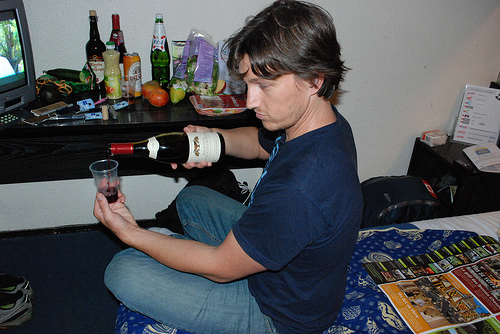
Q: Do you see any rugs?
A: No, there are no rugs.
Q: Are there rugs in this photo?
A: No, there are no rugs.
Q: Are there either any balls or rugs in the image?
A: No, there are no rugs or balls.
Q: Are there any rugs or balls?
A: No, there are no rugs or balls.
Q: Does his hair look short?
A: Yes, the hair is short.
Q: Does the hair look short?
A: Yes, the hair is short.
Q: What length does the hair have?
A: The hair has short length.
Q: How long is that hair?
A: The hair is short.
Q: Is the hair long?
A: No, the hair is short.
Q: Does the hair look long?
A: No, the hair is short.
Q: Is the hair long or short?
A: The hair is short.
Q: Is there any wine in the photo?
A: Yes, there is wine.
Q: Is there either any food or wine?
A: Yes, there is wine.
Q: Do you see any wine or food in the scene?
A: Yes, there is wine.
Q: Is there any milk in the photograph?
A: No, there is no milk.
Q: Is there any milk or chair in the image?
A: No, there are no milk or chairs.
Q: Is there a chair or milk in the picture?
A: No, there are no milk or chairs.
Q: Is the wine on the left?
A: Yes, the wine is on the left of the image.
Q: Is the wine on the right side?
A: No, the wine is on the left of the image.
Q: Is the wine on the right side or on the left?
A: The wine is on the left of the image.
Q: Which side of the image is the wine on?
A: The wine is on the left of the image.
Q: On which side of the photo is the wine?
A: The wine is on the left of the image.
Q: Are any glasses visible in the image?
A: No, there are no glasses.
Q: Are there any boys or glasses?
A: No, there are no glasses or boys.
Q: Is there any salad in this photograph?
A: Yes, there is salad.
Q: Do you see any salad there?
A: Yes, there is salad.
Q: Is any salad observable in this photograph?
A: Yes, there is salad.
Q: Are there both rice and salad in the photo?
A: No, there is salad but no rice.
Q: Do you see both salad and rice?
A: No, there is salad but no rice.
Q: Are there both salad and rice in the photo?
A: No, there is salad but no rice.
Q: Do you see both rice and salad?
A: No, there is salad but no rice.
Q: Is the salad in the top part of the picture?
A: Yes, the salad is in the top of the image.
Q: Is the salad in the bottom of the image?
A: No, the salad is in the top of the image.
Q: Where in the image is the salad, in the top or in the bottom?
A: The salad is in the top of the image.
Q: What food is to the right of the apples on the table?
A: The food is salad.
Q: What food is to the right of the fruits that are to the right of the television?
A: The food is salad.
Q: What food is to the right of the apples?
A: The food is salad.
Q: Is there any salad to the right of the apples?
A: Yes, there is salad to the right of the apples.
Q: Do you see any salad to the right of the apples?
A: Yes, there is salad to the right of the apples.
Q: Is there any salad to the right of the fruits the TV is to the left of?
A: Yes, there is salad to the right of the apples.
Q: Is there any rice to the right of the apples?
A: No, there is salad to the right of the apples.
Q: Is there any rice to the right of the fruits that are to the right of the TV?
A: No, there is salad to the right of the apples.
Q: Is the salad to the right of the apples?
A: Yes, the salad is to the right of the apples.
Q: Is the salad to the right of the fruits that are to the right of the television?
A: Yes, the salad is to the right of the apples.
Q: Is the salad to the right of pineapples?
A: No, the salad is to the right of the apples.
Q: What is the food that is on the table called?
A: The food is salad.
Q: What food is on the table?
A: The food is salad.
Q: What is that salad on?
A: The salad is on the table.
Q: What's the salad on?
A: The salad is on the table.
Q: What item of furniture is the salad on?
A: The salad is on the table.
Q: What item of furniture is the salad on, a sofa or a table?
A: The salad is on a table.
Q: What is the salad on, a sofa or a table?
A: The salad is on a table.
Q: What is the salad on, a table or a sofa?
A: The salad is on a table.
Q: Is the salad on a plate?
A: No, the salad is on the table.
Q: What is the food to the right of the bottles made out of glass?
A: The food is salad.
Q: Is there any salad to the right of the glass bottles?
A: Yes, there is salad to the right of the bottles.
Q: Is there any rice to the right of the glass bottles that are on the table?
A: No, there is salad to the right of the bottles.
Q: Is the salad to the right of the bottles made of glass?
A: Yes, the salad is to the right of the bottles.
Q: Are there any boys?
A: No, there are no boys.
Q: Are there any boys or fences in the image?
A: No, there are no boys or fences.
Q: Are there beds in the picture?
A: Yes, there is a bed.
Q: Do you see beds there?
A: Yes, there is a bed.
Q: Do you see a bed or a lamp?
A: Yes, there is a bed.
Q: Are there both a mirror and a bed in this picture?
A: No, there is a bed but no mirrors.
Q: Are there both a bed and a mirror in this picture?
A: No, there is a bed but no mirrors.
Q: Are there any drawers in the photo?
A: No, there are no drawers.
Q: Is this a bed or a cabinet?
A: This is a bed.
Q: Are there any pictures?
A: No, there are no pictures.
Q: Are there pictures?
A: No, there are no pictures.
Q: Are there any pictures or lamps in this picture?
A: No, there are no pictures or lamps.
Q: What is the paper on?
A: The paper is on the bed.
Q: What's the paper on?
A: The paper is on the bed.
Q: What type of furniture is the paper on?
A: The paper is on the bed.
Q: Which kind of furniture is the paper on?
A: The paper is on the bed.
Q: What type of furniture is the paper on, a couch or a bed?
A: The paper is on a bed.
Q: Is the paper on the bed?
A: Yes, the paper is on the bed.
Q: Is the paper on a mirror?
A: No, the paper is on the bed.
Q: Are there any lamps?
A: No, there are no lamps.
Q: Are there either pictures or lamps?
A: No, there are no lamps or pictures.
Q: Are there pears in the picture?
A: Yes, there is a pear.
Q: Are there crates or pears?
A: Yes, there is a pear.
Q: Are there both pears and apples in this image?
A: Yes, there are both a pear and apples.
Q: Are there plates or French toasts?
A: No, there are no plates or French toasts.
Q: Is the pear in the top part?
A: Yes, the pear is in the top of the image.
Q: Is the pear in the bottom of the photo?
A: No, the pear is in the top of the image.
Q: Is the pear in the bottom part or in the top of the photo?
A: The pear is in the top of the image.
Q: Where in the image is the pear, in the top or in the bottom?
A: The pear is in the top of the image.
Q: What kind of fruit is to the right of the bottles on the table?
A: The fruit is a pear.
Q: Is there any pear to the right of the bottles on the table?
A: Yes, there is a pear to the right of the bottles.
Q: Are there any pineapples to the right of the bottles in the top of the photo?
A: No, there is a pear to the right of the bottles.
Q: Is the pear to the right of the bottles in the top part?
A: Yes, the pear is to the right of the bottles.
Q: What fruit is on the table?
A: The fruit is a pear.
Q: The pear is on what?
A: The pear is on the table.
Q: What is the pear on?
A: The pear is on the table.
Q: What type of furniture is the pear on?
A: The pear is on the table.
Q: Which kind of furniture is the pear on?
A: The pear is on the table.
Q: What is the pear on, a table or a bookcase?
A: The pear is on a table.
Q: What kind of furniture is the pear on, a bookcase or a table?
A: The pear is on a table.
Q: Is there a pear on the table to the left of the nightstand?
A: Yes, there is a pear on the table.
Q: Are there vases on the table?
A: No, there is a pear on the table.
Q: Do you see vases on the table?
A: No, there is a pear on the table.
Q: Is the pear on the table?
A: Yes, the pear is on the table.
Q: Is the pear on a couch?
A: No, the pear is on the table.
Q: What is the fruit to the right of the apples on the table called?
A: The fruit is a pear.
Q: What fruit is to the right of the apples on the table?
A: The fruit is a pear.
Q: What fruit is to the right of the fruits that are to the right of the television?
A: The fruit is a pear.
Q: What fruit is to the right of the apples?
A: The fruit is a pear.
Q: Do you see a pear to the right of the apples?
A: Yes, there is a pear to the right of the apples.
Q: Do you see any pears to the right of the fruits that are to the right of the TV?
A: Yes, there is a pear to the right of the apples.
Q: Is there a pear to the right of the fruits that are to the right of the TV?
A: Yes, there is a pear to the right of the apples.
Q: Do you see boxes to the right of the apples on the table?
A: No, there is a pear to the right of the apples.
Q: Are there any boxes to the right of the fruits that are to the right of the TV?
A: No, there is a pear to the right of the apples.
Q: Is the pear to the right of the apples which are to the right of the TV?
A: Yes, the pear is to the right of the apples.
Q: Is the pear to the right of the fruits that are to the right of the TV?
A: Yes, the pear is to the right of the apples.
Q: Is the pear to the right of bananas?
A: No, the pear is to the right of the apples.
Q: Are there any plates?
A: No, there are no plates.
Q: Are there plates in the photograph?
A: No, there are no plates.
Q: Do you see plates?
A: No, there are no plates.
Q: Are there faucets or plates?
A: No, there are no plates or faucets.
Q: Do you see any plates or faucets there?
A: No, there are no plates or faucets.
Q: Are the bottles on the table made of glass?
A: Yes, the bottles are made of glass.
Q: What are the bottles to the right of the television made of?
A: The bottles are made of glass.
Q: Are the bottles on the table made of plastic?
A: No, the bottles are made of glass.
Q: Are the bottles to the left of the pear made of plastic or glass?
A: The bottles are made of glass.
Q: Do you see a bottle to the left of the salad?
A: Yes, there are bottles to the left of the salad.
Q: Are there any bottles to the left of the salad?
A: Yes, there are bottles to the left of the salad.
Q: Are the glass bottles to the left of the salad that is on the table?
A: Yes, the bottles are to the left of the salad.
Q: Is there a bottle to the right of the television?
A: Yes, there are bottles to the right of the television.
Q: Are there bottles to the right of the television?
A: Yes, there are bottles to the right of the television.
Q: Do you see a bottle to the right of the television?
A: Yes, there are bottles to the right of the television.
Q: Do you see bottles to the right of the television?
A: Yes, there are bottles to the right of the television.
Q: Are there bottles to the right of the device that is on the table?
A: Yes, there are bottles to the right of the television.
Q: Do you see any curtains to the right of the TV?
A: No, there are bottles to the right of the TV.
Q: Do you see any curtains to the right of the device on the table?
A: No, there are bottles to the right of the TV.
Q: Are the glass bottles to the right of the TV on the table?
A: Yes, the bottles are to the right of the television.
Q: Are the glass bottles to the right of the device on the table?
A: Yes, the bottles are to the right of the television.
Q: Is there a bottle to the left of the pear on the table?
A: Yes, there are bottles to the left of the pear.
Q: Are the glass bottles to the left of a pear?
A: Yes, the bottles are to the left of a pear.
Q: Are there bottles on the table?
A: Yes, there are bottles on the table.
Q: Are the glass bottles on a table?
A: Yes, the bottles are on a table.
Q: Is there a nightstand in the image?
A: Yes, there is a nightstand.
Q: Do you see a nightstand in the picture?
A: Yes, there is a nightstand.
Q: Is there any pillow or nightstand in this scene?
A: Yes, there is a nightstand.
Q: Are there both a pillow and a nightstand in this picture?
A: No, there is a nightstand but no pillows.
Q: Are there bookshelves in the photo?
A: No, there are no bookshelves.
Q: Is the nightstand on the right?
A: Yes, the nightstand is on the right of the image.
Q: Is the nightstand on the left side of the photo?
A: No, the nightstand is on the right of the image.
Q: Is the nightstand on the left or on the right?
A: The nightstand is on the right of the image.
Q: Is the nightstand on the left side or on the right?
A: The nightstand is on the right of the image.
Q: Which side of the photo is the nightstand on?
A: The nightstand is on the right of the image.